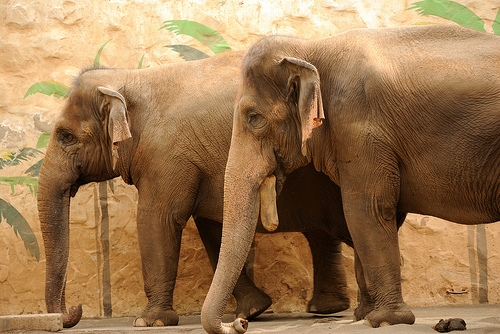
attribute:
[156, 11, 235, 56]
leaves — green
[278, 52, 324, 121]
border — pink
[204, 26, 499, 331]
elephant — brown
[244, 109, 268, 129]
eye — small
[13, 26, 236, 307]
elephant — brown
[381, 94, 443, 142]
skin — grey, wrinkled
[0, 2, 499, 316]
wall — yellow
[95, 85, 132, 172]
ear — large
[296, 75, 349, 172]
ear — shaped like africa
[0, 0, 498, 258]
leaves — green